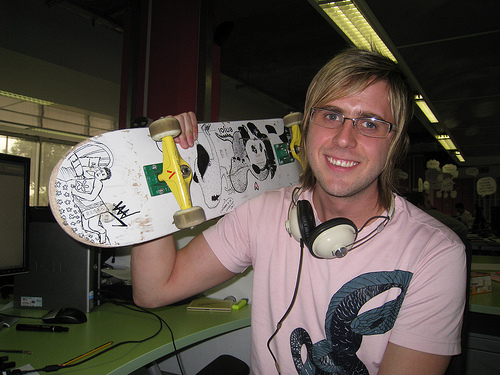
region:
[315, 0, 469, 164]
row of florescent ceiling lights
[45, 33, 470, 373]
man holding a skateboard over his shoulder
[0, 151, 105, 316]
two pieces of computer equipment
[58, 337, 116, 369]
sharpened yellow pencil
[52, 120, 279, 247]
several doodles on bottom of skateboard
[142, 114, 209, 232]
two front wheels of skateboard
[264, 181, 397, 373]
headphones hanging around neck of man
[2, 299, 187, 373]
electronic equipment cables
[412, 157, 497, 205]
cartoon drawings on back wall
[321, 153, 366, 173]
man's smile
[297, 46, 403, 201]
man wearing wire rimmed glasses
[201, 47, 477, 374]
man wearing light pink t shirt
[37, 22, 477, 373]
man holding white patterned skateboard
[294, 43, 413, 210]
blond haired man smiling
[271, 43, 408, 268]
man with large white headphones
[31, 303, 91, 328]
one black and silver computer mouse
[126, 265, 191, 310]
one Caucasian right elbow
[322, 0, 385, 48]
part of industrial fluorescent light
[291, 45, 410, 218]
man with shoulder length blond hair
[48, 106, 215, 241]
right hand gripping skateboard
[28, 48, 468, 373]
a man holding a skateboard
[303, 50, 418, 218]
a man with blonde hair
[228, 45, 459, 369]
a man wearing a pink t-shirt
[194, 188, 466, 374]
a t-shirt with a snake print on it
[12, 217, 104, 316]
a Dell computer case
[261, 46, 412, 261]
a man wearing headphones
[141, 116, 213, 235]
the wheels on a skateboard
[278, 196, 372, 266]
a pair of white headphones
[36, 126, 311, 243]
the bottom of a skateboard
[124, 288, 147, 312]
the elbow of a man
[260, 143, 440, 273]
White headphones on mans neck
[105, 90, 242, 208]
Hand holding white skateboard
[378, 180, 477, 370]
Man has left arm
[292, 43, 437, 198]
Blonde man wearing glasses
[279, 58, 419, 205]
Blonde skateboarder is smiling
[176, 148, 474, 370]
Skateboarder is wearing pink shirt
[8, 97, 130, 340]
Computer tower sitting on desk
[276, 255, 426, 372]
Snake on a pink shirt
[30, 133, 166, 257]
Drawings on a white skateboard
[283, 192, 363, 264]
A black and white headset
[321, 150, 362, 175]
The mouth of the person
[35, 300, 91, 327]
The mouse of the computer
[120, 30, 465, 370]
A person smiling at the camera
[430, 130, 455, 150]
The light on the ceiling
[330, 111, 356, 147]
The person's nose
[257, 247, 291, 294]
Part of the person's T-shirt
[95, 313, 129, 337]
Part of the computer desk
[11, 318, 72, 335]
A black marker on the desk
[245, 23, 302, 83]
Part of the ceiling